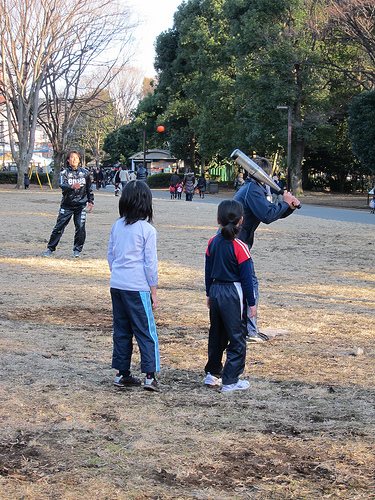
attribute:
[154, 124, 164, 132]
ball — round, orange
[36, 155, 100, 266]
outfit — black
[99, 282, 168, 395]
pant — blue, striped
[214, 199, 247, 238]
hair — black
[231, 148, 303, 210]
bat — silver, metal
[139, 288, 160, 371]
stripe — blue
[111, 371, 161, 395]
sneakers — black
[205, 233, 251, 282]
shirt — long sleeved, light blue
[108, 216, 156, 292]
shirt — light blue, long sleeved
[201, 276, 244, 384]
pants — dark, blue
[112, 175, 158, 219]
hair — long, black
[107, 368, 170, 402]
sneakers — black